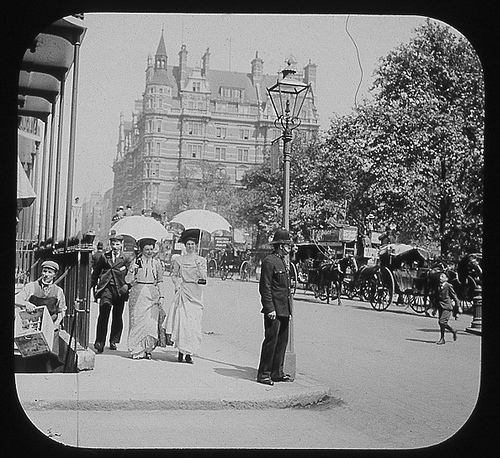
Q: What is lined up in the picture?
A: Horse carriages.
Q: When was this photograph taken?
A: Turn of the century.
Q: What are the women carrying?
A: Umbrellas.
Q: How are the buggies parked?
A: Single file.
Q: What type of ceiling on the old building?
A: Cathedral.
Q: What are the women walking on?
A: Sidewalk.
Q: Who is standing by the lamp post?
A: Police officer.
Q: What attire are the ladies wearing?
A: Dresses.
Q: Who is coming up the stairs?
A: Male worker.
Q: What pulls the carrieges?
A: Horses.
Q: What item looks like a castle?
A: A building.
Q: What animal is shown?
A: A horse.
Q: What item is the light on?
A: A pole.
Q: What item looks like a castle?
A: A building.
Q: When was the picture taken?
A: Daytime.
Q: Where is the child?
A: In the street.